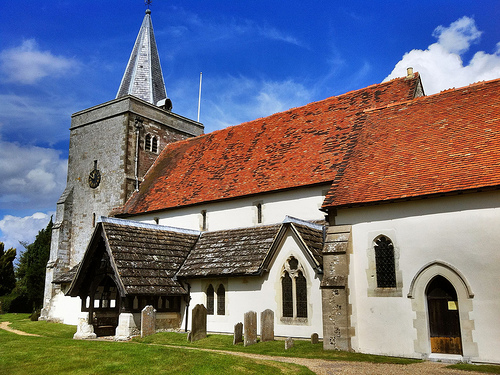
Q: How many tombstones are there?
A: 7.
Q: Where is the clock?
A: On the building.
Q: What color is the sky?
A: Blue.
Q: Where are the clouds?
A: In the sky.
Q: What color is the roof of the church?
A: Red.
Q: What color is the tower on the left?
A: Grey.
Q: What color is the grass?
A: Green.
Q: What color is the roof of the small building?
A: Grey.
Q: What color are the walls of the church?
A: White.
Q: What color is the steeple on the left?
A: Grey.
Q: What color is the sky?
A: Blue.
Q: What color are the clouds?
A: White.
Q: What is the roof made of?
A: Shingles.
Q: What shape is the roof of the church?
A: Slanted.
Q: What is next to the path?
A: Gravestones.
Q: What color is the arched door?
A: Black and yellow.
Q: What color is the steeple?
A: Light grey.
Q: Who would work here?
A: A minister.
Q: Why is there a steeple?
A: This is a church.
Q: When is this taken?
A: During the day.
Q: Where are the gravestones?
A: Next to the church.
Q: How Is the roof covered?
A: With red tiles.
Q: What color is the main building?
A: White.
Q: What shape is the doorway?
A: An arch.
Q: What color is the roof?
A: Red.